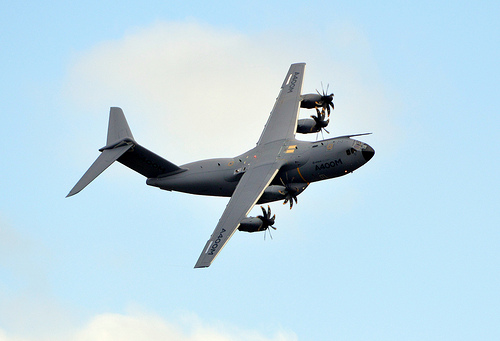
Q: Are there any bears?
A: No, there are no bears.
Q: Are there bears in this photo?
A: No, there are no bears.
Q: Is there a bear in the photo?
A: No, there are no bears.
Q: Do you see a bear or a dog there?
A: No, there are no bears or dogs.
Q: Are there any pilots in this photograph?
A: No, there are no pilots.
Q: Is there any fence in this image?
A: No, there are no fences.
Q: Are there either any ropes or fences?
A: No, there are no fences or ropes.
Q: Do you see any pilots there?
A: No, there are no pilots.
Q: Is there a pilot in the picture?
A: No, there are no pilots.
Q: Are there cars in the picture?
A: No, there are no cars.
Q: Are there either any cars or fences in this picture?
A: No, there are no cars or fences.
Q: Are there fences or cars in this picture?
A: No, there are no cars or fences.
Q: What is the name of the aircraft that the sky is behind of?
A: The aircraft is an airplane.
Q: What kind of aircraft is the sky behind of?
A: The sky is behind the plane.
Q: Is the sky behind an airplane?
A: Yes, the sky is behind an airplane.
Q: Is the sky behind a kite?
A: No, the sky is behind an airplane.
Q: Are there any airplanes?
A: Yes, there is an airplane.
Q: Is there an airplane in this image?
A: Yes, there is an airplane.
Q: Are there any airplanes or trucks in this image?
A: Yes, there is an airplane.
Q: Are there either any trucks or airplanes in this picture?
A: Yes, there is an airplane.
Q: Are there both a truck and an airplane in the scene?
A: No, there is an airplane but no trucks.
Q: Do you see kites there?
A: No, there are no kites.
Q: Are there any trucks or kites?
A: No, there are no kites or trucks.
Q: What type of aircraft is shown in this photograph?
A: The aircraft is an airplane.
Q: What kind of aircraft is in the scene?
A: The aircraft is an airplane.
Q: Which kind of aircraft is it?
A: The aircraft is an airplane.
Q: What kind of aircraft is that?
A: This is an airplane.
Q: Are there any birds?
A: No, there are no birds.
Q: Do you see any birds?
A: No, there are no birds.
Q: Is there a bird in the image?
A: No, there are no birds.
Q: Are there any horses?
A: No, there are no horses.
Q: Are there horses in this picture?
A: No, there are no horses.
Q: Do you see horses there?
A: No, there are no horses.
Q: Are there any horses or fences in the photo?
A: No, there are no horses or fences.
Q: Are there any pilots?
A: No, there are no pilots.